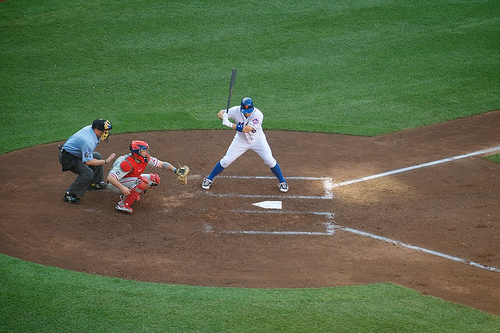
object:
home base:
[251, 200, 284, 210]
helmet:
[240, 97, 253, 113]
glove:
[174, 166, 190, 185]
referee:
[57, 118, 116, 204]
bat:
[227, 70, 239, 114]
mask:
[138, 148, 150, 158]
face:
[138, 148, 148, 158]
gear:
[125, 156, 159, 193]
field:
[0, 0, 500, 333]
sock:
[269, 163, 286, 182]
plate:
[252, 200, 282, 210]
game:
[33, 17, 439, 296]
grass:
[0, 1, 500, 152]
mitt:
[174, 165, 190, 186]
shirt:
[61, 125, 99, 163]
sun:
[320, 165, 374, 191]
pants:
[218, 134, 276, 168]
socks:
[207, 162, 225, 181]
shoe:
[278, 181, 289, 191]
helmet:
[130, 140, 148, 153]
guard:
[121, 156, 160, 210]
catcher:
[106, 140, 189, 215]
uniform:
[105, 153, 160, 206]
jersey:
[227, 105, 267, 142]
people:
[200, 97, 288, 193]